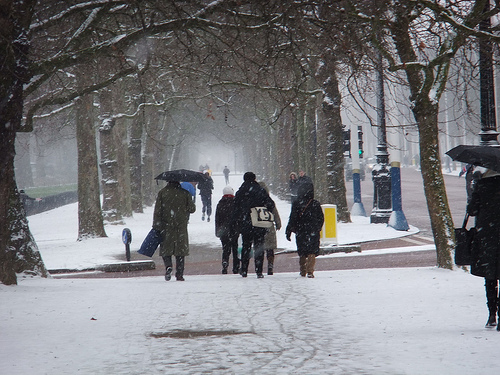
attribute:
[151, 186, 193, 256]
coat — long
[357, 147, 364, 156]
signal — green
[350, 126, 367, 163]
light — green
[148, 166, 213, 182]
umbrella — black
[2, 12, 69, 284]
tree — large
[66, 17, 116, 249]
tree — large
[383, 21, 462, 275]
tree — large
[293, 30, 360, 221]
tree — large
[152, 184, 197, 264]
coat — dark green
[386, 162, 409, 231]
post — blue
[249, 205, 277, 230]
bag — white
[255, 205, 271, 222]
face — black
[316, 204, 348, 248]
box — yellow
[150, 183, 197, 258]
trench coat — long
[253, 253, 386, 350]
snow — white , falling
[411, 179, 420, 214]
asphalt — black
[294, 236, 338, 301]
boots — brown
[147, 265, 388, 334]
sidewalk — white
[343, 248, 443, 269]
concrete — red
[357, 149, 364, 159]
light — lit , green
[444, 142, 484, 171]
umbrella — black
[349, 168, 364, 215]
post — blue